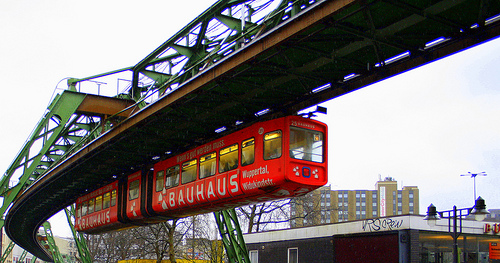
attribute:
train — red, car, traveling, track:
[62, 91, 341, 253]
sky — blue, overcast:
[88, 23, 122, 47]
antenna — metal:
[460, 160, 485, 205]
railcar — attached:
[51, 75, 350, 259]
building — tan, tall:
[317, 175, 425, 223]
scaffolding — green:
[30, 74, 96, 162]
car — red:
[53, 84, 344, 254]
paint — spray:
[152, 164, 275, 223]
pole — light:
[405, 180, 494, 263]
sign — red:
[287, 162, 328, 187]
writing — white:
[237, 155, 278, 186]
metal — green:
[52, 91, 90, 139]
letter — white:
[192, 153, 275, 218]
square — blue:
[298, 161, 316, 176]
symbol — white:
[286, 156, 306, 181]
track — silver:
[189, 76, 323, 159]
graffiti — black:
[355, 211, 406, 238]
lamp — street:
[417, 184, 490, 254]